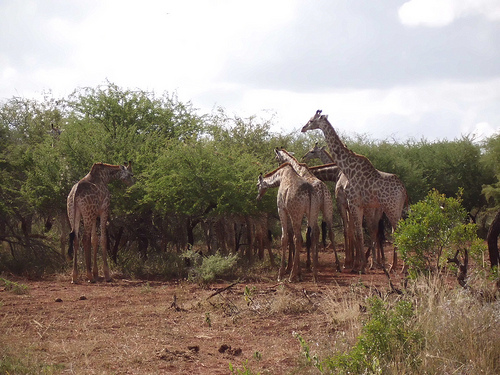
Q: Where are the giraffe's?
A: In a field.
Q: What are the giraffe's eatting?
A: Leaves.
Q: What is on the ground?
A: Dirt.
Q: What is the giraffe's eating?
A: Plants.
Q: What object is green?
A: The trees.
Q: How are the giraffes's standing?
A: I a group.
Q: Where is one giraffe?
A: Standing alone.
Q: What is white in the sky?
A: The clouds.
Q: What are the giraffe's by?
A: Trees.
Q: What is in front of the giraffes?
A: A dirt patch.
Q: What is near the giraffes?
A: The trees.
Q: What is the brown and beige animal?
A: The giraffe.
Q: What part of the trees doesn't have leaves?
A: The bottom.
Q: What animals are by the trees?
A: Giraffes.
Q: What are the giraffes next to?
A: Trees.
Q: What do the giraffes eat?
A: Leaves.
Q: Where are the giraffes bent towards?
A: Trees.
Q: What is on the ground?
A: Dry grass.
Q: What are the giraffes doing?
A: Eating.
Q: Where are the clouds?
A: In the sky.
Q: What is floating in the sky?
A: Clouds.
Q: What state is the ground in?
A: Dry.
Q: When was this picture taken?
A: Daytime.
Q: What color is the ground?
A: Brown.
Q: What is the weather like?
A: Cloudy.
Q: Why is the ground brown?
A: All the grass is dead.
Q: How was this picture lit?
A: Sunlight.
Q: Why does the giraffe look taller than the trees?
A: Forced perspective.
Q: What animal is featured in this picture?
A: Giraffe.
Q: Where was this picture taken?
A: In a wildlife preserve.